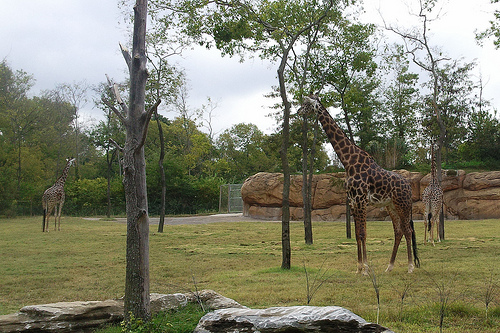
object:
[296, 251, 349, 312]
shrubs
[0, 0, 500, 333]
enclosure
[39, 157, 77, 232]
giraffe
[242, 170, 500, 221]
wall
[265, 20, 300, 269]
trunk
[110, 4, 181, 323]
tree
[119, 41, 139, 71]
branch stumps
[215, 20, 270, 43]
leaves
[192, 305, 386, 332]
large rock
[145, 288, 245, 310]
large rock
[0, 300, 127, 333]
large rock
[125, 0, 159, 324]
tree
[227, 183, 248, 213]
fencing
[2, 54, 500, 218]
forest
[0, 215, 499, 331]
grass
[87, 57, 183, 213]
many trees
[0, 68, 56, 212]
delicate trees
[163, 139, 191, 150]
green leaves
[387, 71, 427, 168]
trees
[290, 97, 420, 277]
giraffe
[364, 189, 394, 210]
stomach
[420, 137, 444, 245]
giraffe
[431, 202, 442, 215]
stomach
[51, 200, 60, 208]
stomach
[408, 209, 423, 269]
tail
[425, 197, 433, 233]
tail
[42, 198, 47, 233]
tail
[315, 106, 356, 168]
neck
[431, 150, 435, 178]
neck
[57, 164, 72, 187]
neck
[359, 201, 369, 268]
leg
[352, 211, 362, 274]
leg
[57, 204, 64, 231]
leg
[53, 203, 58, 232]
leg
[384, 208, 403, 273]
leg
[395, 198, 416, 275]
leg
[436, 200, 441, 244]
leg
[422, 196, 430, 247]
leg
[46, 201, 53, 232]
leg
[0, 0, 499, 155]
sky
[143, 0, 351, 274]
tree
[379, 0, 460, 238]
tree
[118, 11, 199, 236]
tree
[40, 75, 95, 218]
tree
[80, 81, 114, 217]
tree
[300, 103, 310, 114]
face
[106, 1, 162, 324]
trunk